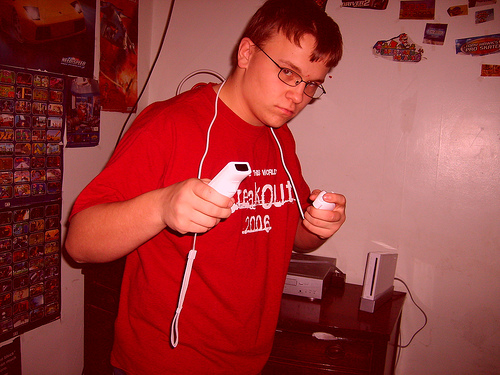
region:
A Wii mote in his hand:
[210, 157, 246, 214]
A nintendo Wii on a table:
[367, 246, 395, 316]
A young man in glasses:
[244, 4, 330, 128]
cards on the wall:
[3, 156, 50, 220]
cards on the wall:
[5, 70, 44, 110]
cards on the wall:
[47, 125, 63, 195]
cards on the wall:
[2, 210, 39, 257]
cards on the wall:
[27, 267, 61, 320]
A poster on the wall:
[0, 10, 102, 75]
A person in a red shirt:
[96, 78, 275, 373]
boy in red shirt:
[62, 2, 346, 371]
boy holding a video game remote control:
[77, 0, 349, 374]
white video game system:
[352, 234, 432, 352]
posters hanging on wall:
[0, 1, 150, 373]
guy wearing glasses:
[65, 3, 354, 373]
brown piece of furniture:
[82, 248, 414, 373]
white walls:
[1, 0, 496, 372]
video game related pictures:
[330, 0, 498, 94]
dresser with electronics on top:
[77, 233, 416, 373]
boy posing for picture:
[57, 0, 356, 373]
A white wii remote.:
[208, 160, 252, 199]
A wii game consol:
[360, 250, 397, 320]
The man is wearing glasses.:
[274, 66, 326, 102]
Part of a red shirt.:
[141, 119, 193, 168]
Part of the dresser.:
[297, 317, 392, 373]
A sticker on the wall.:
[370, 30, 425, 67]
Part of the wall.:
[371, 137, 486, 204]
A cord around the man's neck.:
[192, 79, 287, 175]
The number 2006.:
[242, 213, 272, 235]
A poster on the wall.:
[3, 0, 95, 77]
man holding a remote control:
[61, 2, 347, 374]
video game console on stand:
[358, 246, 406, 315]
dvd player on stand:
[282, 252, 343, 297]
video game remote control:
[183, 161, 251, 214]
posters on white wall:
[0, 0, 139, 318]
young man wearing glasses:
[66, 3, 311, 373]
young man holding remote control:
[62, 1, 347, 373]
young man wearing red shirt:
[61, 2, 341, 374]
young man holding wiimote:
[63, 1, 353, 373]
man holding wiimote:
[62, 3, 348, 373]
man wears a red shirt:
[53, 0, 380, 370]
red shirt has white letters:
[76, 84, 343, 374]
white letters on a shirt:
[143, 105, 328, 274]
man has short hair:
[189, 3, 354, 170]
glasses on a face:
[236, 23, 345, 118]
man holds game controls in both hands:
[55, 9, 373, 340]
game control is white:
[162, 71, 351, 352]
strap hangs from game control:
[161, 152, 257, 353]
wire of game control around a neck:
[146, 0, 376, 267]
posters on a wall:
[3, 4, 160, 145]